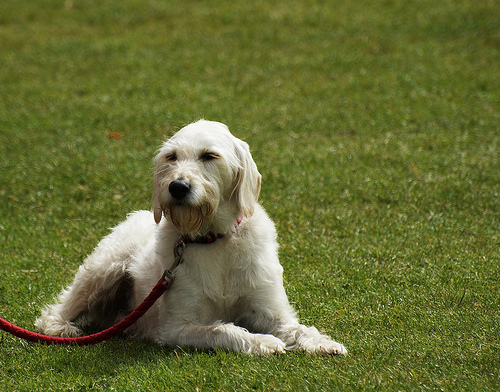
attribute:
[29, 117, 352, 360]
dog — white, laying down, lying down, mostly white, long haired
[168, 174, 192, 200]
nose — black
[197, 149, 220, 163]
eye — black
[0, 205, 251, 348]
leash — red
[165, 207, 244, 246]
collar — red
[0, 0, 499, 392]
grass — green, in the picture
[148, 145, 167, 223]
right ear — floppy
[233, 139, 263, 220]
left ear — down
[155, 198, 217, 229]
mouth hair — dirty, stained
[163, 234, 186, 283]
buckle — silver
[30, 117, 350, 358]
fur — white, long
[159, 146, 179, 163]
eye — black, dark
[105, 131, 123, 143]
leaf — brown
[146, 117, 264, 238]
head — turned